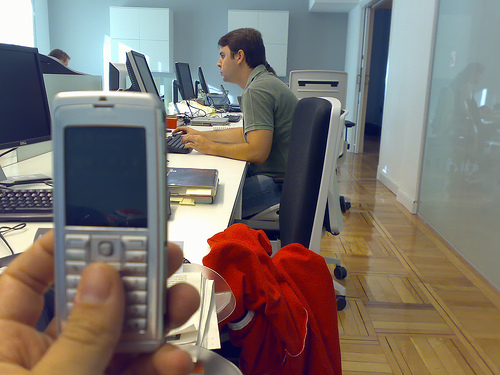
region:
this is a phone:
[52, 92, 163, 352]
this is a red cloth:
[200, 220, 351, 371]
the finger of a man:
[25, 265, 131, 368]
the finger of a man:
[145, 345, 188, 371]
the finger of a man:
[162, 287, 212, 323]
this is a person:
[170, 31, 331, 214]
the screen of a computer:
[118, 41, 173, 117]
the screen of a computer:
[161, 42, 201, 112]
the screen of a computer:
[190, 52, 220, 102]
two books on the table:
[162, 162, 243, 212]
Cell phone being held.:
[39, 86, 171, 353]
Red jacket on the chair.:
[201, 222, 350, 372]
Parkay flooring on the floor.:
[309, 141, 494, 373]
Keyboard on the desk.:
[1, 186, 63, 226]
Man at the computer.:
[176, 27, 306, 221]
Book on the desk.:
[163, 162, 219, 209]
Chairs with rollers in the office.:
[251, 96, 361, 317]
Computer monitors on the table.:
[99, 42, 222, 114]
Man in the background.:
[40, 46, 75, 75]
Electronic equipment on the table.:
[152, 90, 244, 165]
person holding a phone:
[5, 77, 187, 370]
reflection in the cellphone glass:
[46, 121, 158, 233]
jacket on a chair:
[187, 202, 338, 349]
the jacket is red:
[185, 211, 354, 363]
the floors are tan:
[357, 227, 477, 337]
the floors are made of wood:
[365, 215, 490, 361]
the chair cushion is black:
[261, 89, 332, 254]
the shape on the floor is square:
[332, 223, 467, 367]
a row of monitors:
[2, 42, 231, 149]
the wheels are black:
[331, 253, 360, 315]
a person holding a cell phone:
[28, 56, 192, 373]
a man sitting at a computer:
[151, 22, 282, 188]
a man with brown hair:
[202, 25, 264, 93]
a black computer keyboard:
[1, 170, 54, 229]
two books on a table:
[180, 157, 225, 218]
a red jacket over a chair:
[226, 222, 372, 372]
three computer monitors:
[128, 64, 209, 101]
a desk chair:
[251, 85, 351, 271]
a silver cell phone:
[51, 81, 193, 355]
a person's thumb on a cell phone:
[38, 163, 179, 371]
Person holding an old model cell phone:
[25, 70, 183, 355]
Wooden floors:
[352, 205, 490, 338]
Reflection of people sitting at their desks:
[430, 20, 496, 241]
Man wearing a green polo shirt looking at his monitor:
[207, 40, 329, 197]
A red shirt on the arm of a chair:
[207, 215, 338, 347]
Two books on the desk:
[148, 135, 223, 220]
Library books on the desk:
[145, 145, 228, 220]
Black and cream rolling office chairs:
[280, 93, 363, 310]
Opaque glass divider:
[370, 47, 495, 247]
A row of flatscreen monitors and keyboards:
[3, 48, 230, 236]